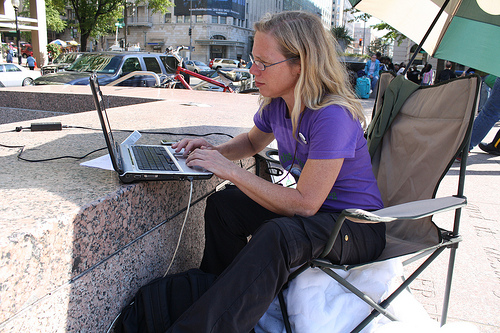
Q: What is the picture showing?
A: It is showing a street.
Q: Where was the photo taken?
A: It was taken at the street.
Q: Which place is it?
A: It is a street.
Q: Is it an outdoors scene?
A: Yes, it is outdoors.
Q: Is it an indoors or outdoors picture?
A: It is outdoors.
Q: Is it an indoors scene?
A: No, it is outdoors.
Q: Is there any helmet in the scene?
A: No, there are no helmets.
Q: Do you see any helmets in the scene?
A: No, there are no helmets.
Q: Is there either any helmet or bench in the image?
A: No, there are no helmets or benches.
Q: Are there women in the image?
A: Yes, there is a woman.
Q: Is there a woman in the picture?
A: Yes, there is a woman.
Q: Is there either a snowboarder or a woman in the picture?
A: Yes, there is a woman.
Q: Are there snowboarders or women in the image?
A: Yes, there is a woman.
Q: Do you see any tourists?
A: No, there are no tourists.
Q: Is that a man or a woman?
A: That is a woman.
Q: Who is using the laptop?
A: The woman is using the laptop.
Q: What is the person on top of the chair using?
A: The woman is using a laptop.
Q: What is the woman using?
A: The woman is using a laptop.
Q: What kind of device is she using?
A: The woman is using a laptop.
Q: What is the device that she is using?
A: The device is a laptop.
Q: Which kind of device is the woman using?
A: The woman is using a laptop.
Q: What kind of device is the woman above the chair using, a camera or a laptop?
A: The woman is using a laptop.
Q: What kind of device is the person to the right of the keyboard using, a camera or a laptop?
A: The woman is using a laptop.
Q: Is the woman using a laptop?
A: Yes, the woman is using a laptop.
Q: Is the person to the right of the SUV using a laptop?
A: Yes, the woman is using a laptop.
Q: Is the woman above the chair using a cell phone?
A: No, the woman is using a laptop.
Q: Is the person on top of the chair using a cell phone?
A: No, the woman is using a laptop.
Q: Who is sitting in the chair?
A: The woman is sitting in the chair.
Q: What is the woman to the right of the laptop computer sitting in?
A: The woman is sitting in the chair.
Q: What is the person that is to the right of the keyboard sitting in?
A: The woman is sitting in the chair.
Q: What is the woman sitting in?
A: The woman is sitting in the chair.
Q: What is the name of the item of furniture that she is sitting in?
A: The piece of furniture is a chair.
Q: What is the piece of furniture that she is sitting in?
A: The piece of furniture is a chair.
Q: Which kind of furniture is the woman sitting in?
A: The woman is sitting in the chair.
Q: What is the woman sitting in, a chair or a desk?
A: The woman is sitting in a chair.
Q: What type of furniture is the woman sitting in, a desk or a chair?
A: The woman is sitting in a chair.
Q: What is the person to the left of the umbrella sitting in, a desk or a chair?
A: The woman is sitting in a chair.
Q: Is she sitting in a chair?
A: Yes, the woman is sitting in a chair.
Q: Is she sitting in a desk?
A: No, the woman is sitting in a chair.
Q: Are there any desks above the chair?
A: No, there is a woman above the chair.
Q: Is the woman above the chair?
A: Yes, the woman is above the chair.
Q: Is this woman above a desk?
A: No, the woman is above the chair.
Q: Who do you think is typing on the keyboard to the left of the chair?
A: The woman is typing on the keyboard.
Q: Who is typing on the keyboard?
A: The woman is typing on the keyboard.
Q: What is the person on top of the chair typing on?
A: The woman is typing on the keyboard.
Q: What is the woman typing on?
A: The woman is typing on the keyboard.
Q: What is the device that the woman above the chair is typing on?
A: The device is a keyboard.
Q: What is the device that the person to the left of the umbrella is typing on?
A: The device is a keyboard.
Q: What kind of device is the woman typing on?
A: The woman is typing on the keyboard.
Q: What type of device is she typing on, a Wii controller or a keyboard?
A: The woman is typing on a keyboard.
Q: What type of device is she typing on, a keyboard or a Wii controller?
A: The woman is typing on a keyboard.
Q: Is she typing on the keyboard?
A: Yes, the woman is typing on the keyboard.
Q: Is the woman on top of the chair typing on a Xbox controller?
A: No, the woman is typing on the keyboard.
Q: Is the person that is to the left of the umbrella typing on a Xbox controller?
A: No, the woman is typing on the keyboard.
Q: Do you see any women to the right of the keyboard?
A: Yes, there is a woman to the right of the keyboard.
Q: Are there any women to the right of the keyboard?
A: Yes, there is a woman to the right of the keyboard.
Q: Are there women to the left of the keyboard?
A: No, the woman is to the right of the keyboard.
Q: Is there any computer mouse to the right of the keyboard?
A: No, there is a woman to the right of the keyboard.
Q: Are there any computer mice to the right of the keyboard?
A: No, there is a woman to the right of the keyboard.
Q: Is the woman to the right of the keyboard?
A: Yes, the woman is to the right of the keyboard.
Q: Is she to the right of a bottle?
A: No, the woman is to the right of the keyboard.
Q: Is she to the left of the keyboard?
A: No, the woman is to the right of the keyboard.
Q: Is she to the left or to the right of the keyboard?
A: The woman is to the right of the keyboard.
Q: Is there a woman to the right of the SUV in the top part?
A: Yes, there is a woman to the right of the SUV.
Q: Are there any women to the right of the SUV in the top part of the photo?
A: Yes, there is a woman to the right of the SUV.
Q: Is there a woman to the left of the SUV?
A: No, the woman is to the right of the SUV.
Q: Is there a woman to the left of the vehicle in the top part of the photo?
A: No, the woman is to the right of the SUV.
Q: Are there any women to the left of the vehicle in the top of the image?
A: No, the woman is to the right of the SUV.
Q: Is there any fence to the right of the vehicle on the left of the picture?
A: No, there is a woman to the right of the SUV.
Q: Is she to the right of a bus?
A: No, the woman is to the right of the SUV.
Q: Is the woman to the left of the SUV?
A: No, the woman is to the right of the SUV.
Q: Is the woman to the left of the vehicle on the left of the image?
A: No, the woman is to the right of the SUV.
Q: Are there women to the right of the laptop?
A: Yes, there is a woman to the right of the laptop.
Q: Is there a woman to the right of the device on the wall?
A: Yes, there is a woman to the right of the laptop.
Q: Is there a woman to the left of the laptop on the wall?
A: No, the woman is to the right of the laptop.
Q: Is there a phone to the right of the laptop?
A: No, there is a woman to the right of the laptop.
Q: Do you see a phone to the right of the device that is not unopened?
A: No, there is a woman to the right of the laptop.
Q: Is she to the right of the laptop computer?
A: Yes, the woman is to the right of the laptop computer.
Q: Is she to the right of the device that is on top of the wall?
A: Yes, the woman is to the right of the laptop computer.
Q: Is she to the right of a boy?
A: No, the woman is to the right of the laptop computer.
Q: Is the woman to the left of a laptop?
A: No, the woman is to the right of a laptop.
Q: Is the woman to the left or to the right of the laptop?
A: The woman is to the right of the laptop.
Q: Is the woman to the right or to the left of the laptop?
A: The woman is to the right of the laptop.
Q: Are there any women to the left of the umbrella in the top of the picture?
A: Yes, there is a woman to the left of the umbrella.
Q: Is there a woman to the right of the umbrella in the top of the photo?
A: No, the woman is to the left of the umbrella.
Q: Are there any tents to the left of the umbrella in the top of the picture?
A: No, there is a woman to the left of the umbrella.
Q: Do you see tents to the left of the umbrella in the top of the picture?
A: No, there is a woman to the left of the umbrella.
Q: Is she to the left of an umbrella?
A: Yes, the woman is to the left of an umbrella.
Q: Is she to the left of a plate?
A: No, the woman is to the left of an umbrella.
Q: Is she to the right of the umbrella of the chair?
A: No, the woman is to the left of the umbrella.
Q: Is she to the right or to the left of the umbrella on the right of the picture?
A: The woman is to the left of the umbrella.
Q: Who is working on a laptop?
A: The woman is working on a laptop.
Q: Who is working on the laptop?
A: The woman is working on a laptop.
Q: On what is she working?
A: The woman is working on a laptop.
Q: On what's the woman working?
A: The woman is working on a laptop.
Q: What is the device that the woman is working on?
A: The device is a laptop.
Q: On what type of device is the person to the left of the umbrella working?
A: The woman is working on a laptop computer.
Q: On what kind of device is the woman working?
A: The woman is working on a laptop computer.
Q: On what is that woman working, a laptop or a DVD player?
A: The woman is working on a laptop.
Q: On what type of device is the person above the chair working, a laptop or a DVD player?
A: The woman is working on a laptop.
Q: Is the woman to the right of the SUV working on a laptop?
A: Yes, the woman is working on a laptop.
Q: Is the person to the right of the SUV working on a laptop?
A: Yes, the woman is working on a laptop.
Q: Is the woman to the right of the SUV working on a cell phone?
A: No, the woman is working on a laptop.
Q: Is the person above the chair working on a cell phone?
A: No, the woman is working on a laptop.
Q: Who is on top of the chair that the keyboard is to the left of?
A: The woman is on top of the chair.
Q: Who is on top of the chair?
A: The woman is on top of the chair.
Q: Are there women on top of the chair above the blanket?
A: Yes, there is a woman on top of the chair.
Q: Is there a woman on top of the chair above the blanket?
A: Yes, there is a woman on top of the chair.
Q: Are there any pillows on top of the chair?
A: No, there is a woman on top of the chair.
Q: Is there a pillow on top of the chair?
A: No, there is a woman on top of the chair.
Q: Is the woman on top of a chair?
A: Yes, the woman is on top of a chair.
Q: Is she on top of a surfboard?
A: No, the woman is on top of a chair.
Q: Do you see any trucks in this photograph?
A: No, there are no trucks.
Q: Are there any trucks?
A: No, there are no trucks.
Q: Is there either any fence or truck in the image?
A: No, there are no trucks or fences.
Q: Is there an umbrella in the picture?
A: Yes, there is an umbrella.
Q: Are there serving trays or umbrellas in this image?
A: Yes, there is an umbrella.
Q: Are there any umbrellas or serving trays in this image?
A: Yes, there is an umbrella.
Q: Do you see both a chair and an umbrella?
A: Yes, there are both an umbrella and a chair.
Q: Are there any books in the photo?
A: No, there are no books.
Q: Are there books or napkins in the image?
A: No, there are no books or napkins.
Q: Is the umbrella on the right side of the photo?
A: Yes, the umbrella is on the right of the image.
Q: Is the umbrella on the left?
A: No, the umbrella is on the right of the image.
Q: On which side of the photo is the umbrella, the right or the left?
A: The umbrella is on the right of the image.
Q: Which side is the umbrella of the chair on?
A: The umbrella is on the right of the image.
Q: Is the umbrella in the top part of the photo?
A: Yes, the umbrella is in the top of the image.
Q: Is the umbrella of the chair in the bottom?
A: No, the umbrella is in the top of the image.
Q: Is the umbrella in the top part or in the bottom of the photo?
A: The umbrella is in the top of the image.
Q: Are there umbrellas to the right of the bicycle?
A: Yes, there is an umbrella to the right of the bicycle.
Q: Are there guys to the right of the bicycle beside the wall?
A: No, there is an umbrella to the right of the bicycle.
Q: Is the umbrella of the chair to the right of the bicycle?
A: Yes, the umbrella is to the right of the bicycle.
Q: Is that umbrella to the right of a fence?
A: No, the umbrella is to the right of the bicycle.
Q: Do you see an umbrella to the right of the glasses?
A: Yes, there is an umbrella to the right of the glasses.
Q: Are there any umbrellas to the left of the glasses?
A: No, the umbrella is to the right of the glasses.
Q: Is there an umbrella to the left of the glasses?
A: No, the umbrella is to the right of the glasses.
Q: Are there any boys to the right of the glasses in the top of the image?
A: No, there is an umbrella to the right of the glasses.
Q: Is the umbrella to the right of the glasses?
A: Yes, the umbrella is to the right of the glasses.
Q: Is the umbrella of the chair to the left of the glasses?
A: No, the umbrella is to the right of the glasses.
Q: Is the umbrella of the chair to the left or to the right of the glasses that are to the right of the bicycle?
A: The umbrella is to the right of the glasses.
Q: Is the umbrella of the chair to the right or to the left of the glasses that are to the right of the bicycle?
A: The umbrella is to the right of the glasses.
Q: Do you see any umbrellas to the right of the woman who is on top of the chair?
A: Yes, there is an umbrella to the right of the woman.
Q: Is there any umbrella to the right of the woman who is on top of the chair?
A: Yes, there is an umbrella to the right of the woman.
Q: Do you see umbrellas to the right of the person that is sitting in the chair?
A: Yes, there is an umbrella to the right of the woman.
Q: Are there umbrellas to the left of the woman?
A: No, the umbrella is to the right of the woman.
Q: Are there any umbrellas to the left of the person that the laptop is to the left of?
A: No, the umbrella is to the right of the woman.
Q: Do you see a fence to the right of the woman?
A: No, there is an umbrella to the right of the woman.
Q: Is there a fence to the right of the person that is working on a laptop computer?
A: No, there is an umbrella to the right of the woman.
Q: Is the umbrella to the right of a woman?
A: Yes, the umbrella is to the right of a woman.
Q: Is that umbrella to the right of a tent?
A: No, the umbrella is to the right of a woman.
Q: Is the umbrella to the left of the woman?
A: No, the umbrella is to the right of the woman.